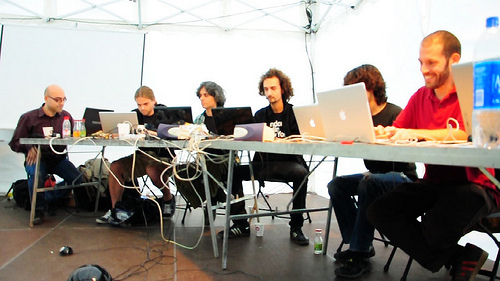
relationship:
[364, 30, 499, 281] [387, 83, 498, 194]
man with shirt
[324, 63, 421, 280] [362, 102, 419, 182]
man in a shirt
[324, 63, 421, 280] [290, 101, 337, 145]
man in front of laptop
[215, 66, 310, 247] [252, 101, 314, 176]
man in shirt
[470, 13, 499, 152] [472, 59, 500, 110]
bottle with sticker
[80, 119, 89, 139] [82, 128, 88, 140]
bottle with sticker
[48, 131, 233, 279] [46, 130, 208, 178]
bunch of wires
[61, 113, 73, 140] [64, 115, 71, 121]
bottle with cap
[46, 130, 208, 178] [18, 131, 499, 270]
wires from table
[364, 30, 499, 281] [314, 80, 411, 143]
man behind computers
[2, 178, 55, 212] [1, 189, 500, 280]
bag on floor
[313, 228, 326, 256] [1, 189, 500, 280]
bottle on floor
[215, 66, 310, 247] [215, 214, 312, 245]
man has shoes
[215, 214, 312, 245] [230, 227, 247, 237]
shoes have stripes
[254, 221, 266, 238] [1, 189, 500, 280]
cup on floor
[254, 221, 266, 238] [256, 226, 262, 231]
cup with design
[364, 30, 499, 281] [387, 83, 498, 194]
man with a shirt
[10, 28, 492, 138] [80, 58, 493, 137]
men on laptops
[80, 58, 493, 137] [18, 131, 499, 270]
laptops on table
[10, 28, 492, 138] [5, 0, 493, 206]
men inside tent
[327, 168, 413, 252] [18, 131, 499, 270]
jeans under table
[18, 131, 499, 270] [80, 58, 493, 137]
table has laptops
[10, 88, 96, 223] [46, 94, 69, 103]
men with glasses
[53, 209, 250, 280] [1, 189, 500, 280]
wires on floor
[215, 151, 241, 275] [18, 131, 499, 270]
leg of table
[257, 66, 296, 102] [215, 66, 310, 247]
hair of man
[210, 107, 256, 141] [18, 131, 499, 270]
laptop on table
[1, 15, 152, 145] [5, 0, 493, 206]
section of tent